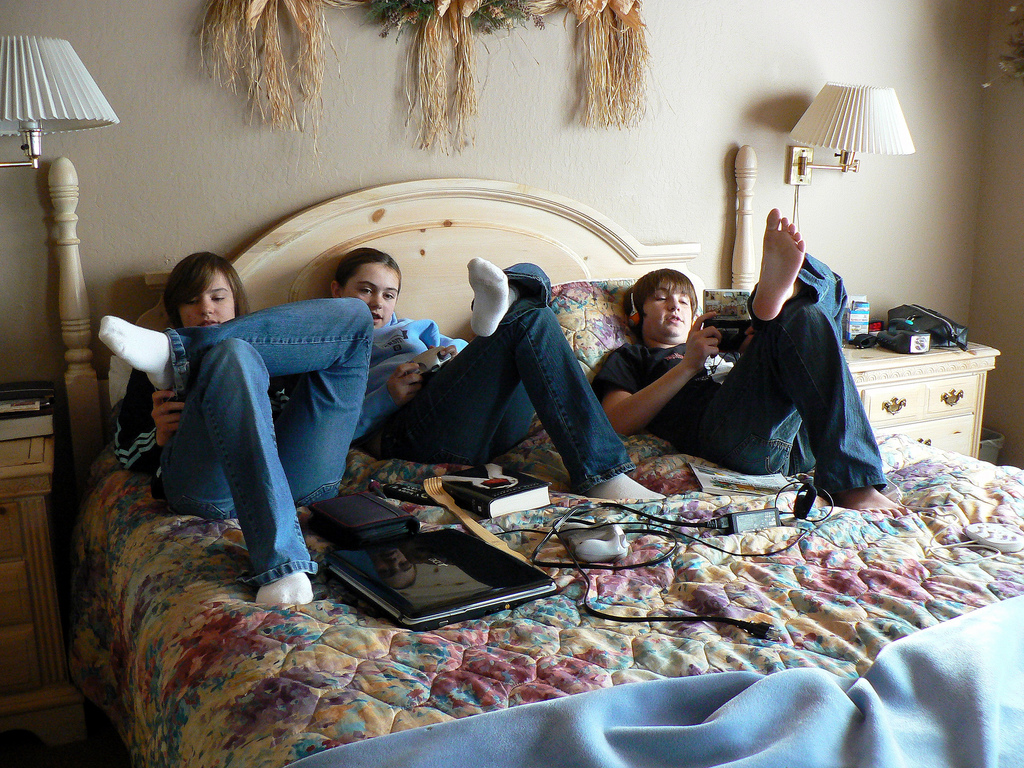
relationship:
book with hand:
[431, 451, 553, 523] [430, 464, 517, 499]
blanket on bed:
[288, 585, 1021, 765] [39, 144, 1022, 765]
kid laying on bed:
[91, 250, 372, 613] [39, 144, 1022, 765]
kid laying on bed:
[325, 250, 665, 503] [39, 144, 1022, 765]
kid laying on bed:
[586, 206, 911, 520] [39, 144, 1022, 765]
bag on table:
[882, 299, 967, 354] [846, 325, 1002, 474]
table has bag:
[835, 340, 1002, 461] [888, 306, 972, 349]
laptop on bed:
[316, 524, 559, 633] [39, 144, 1022, 765]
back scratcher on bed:
[417, 470, 536, 564] [39, 144, 1022, 765]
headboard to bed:
[209, 181, 701, 360] [39, 144, 1022, 765]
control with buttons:
[546, 501, 730, 606] [359, 442, 546, 550]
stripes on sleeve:
[106, 414, 160, 468] [109, 373, 160, 473]